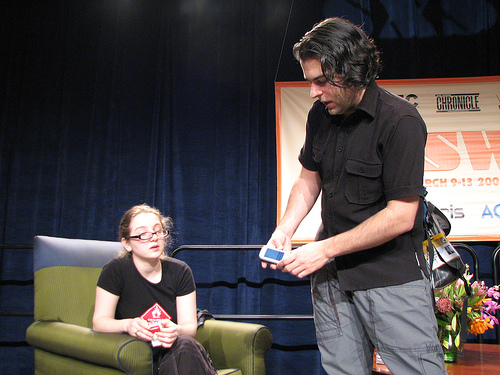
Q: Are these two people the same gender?
A: No, they are both male and female.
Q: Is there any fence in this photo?
A: No, there are no fences.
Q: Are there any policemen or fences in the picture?
A: No, there are no fences or policemen.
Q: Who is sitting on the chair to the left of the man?
A: The girl is sitting on the chair.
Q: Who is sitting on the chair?
A: The girl is sitting on the chair.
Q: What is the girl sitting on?
A: The girl is sitting on the chair.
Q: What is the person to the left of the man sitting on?
A: The girl is sitting on the chair.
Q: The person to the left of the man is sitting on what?
A: The girl is sitting on the chair.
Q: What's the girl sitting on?
A: The girl is sitting on the chair.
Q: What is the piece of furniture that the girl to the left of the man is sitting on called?
A: The piece of furniture is a chair.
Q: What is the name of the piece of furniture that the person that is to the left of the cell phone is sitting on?
A: The piece of furniture is a chair.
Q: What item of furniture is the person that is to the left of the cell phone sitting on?
A: The girl is sitting on the chair.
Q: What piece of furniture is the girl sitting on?
A: The girl is sitting on the chair.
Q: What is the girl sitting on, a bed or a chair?
A: The girl is sitting on a chair.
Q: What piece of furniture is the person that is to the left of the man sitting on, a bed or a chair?
A: The girl is sitting on a chair.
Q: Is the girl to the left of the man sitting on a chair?
A: Yes, the girl is sitting on a chair.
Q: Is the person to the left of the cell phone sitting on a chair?
A: Yes, the girl is sitting on a chair.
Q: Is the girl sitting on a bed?
A: No, the girl is sitting on a chair.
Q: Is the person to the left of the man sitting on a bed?
A: No, the girl is sitting on a chair.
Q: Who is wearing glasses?
A: The girl is wearing glasses.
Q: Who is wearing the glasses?
A: The girl is wearing glasses.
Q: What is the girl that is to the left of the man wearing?
A: The girl is wearing glasses.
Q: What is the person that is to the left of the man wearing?
A: The girl is wearing glasses.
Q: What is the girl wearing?
A: The girl is wearing glasses.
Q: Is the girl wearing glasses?
A: Yes, the girl is wearing glasses.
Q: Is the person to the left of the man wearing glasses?
A: Yes, the girl is wearing glasses.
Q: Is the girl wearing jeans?
A: No, the girl is wearing glasses.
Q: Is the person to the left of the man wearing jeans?
A: No, the girl is wearing glasses.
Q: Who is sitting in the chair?
A: The girl is sitting in the chair.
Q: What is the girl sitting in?
A: The girl is sitting in the chair.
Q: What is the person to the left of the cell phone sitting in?
A: The girl is sitting in the chair.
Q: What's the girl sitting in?
A: The girl is sitting in the chair.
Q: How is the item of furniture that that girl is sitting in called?
A: The piece of furniture is a chair.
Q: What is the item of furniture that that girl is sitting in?
A: The piece of furniture is a chair.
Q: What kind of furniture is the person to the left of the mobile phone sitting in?
A: The girl is sitting in the chair.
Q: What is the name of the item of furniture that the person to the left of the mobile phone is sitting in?
A: The piece of furniture is a chair.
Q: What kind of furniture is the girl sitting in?
A: The girl is sitting in the chair.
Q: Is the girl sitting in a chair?
A: Yes, the girl is sitting in a chair.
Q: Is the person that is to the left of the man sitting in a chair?
A: Yes, the girl is sitting in a chair.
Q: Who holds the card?
A: The girl holds the card.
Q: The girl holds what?
A: The girl holds the card.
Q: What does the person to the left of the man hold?
A: The girl holds the card.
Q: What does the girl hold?
A: The girl holds the card.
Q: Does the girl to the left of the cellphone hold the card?
A: Yes, the girl holds the card.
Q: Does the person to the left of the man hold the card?
A: Yes, the girl holds the card.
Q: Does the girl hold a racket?
A: No, the girl holds the card.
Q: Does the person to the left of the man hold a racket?
A: No, the girl holds the card.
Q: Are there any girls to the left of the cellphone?
A: Yes, there is a girl to the left of the cellphone.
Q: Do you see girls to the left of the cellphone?
A: Yes, there is a girl to the left of the cellphone.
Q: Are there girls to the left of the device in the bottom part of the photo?
A: Yes, there is a girl to the left of the cellphone.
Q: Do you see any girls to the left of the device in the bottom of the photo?
A: Yes, there is a girl to the left of the cellphone.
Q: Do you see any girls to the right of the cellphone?
A: No, the girl is to the left of the cellphone.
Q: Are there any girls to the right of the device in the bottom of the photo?
A: No, the girl is to the left of the cellphone.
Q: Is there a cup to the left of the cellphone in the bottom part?
A: No, there is a girl to the left of the cellphone.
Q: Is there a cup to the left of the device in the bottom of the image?
A: No, there is a girl to the left of the cellphone.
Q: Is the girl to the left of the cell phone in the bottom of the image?
A: Yes, the girl is to the left of the mobile phone.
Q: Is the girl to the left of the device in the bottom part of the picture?
A: Yes, the girl is to the left of the mobile phone.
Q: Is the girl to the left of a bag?
A: No, the girl is to the left of the mobile phone.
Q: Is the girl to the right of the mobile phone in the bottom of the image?
A: No, the girl is to the left of the mobile phone.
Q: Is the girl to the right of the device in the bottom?
A: No, the girl is to the left of the mobile phone.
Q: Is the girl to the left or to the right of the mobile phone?
A: The girl is to the left of the mobile phone.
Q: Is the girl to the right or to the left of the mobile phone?
A: The girl is to the left of the mobile phone.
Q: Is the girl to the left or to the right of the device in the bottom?
A: The girl is to the left of the mobile phone.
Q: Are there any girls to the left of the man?
A: Yes, there is a girl to the left of the man.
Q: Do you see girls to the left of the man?
A: Yes, there is a girl to the left of the man.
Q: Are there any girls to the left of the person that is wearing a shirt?
A: Yes, there is a girl to the left of the man.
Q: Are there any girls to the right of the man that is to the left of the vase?
A: No, the girl is to the left of the man.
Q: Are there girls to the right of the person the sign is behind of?
A: No, the girl is to the left of the man.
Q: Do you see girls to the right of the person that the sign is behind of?
A: No, the girl is to the left of the man.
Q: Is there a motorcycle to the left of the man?
A: No, there is a girl to the left of the man.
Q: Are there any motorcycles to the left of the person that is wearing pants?
A: No, there is a girl to the left of the man.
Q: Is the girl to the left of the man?
A: Yes, the girl is to the left of the man.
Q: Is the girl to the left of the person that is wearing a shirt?
A: Yes, the girl is to the left of the man.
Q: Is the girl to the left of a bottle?
A: No, the girl is to the left of the man.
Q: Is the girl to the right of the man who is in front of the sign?
A: No, the girl is to the left of the man.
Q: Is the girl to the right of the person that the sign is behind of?
A: No, the girl is to the left of the man.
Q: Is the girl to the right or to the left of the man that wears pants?
A: The girl is to the left of the man.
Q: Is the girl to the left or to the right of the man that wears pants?
A: The girl is to the left of the man.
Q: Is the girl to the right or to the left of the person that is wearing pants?
A: The girl is to the left of the man.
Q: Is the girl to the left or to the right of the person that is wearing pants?
A: The girl is to the left of the man.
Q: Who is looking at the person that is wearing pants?
A: The girl is looking at the man.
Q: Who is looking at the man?
A: The girl is looking at the man.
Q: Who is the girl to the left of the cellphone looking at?
A: The girl is looking at the man.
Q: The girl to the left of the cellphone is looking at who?
A: The girl is looking at the man.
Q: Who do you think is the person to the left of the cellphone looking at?
A: The girl is looking at the man.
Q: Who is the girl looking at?
A: The girl is looking at the man.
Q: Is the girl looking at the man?
A: Yes, the girl is looking at the man.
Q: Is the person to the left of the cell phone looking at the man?
A: Yes, the girl is looking at the man.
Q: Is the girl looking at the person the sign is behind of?
A: Yes, the girl is looking at the man.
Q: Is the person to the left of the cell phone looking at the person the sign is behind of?
A: Yes, the girl is looking at the man.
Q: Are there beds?
A: No, there are no beds.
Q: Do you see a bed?
A: No, there are no beds.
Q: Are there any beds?
A: No, there are no beds.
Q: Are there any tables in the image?
A: Yes, there is a table.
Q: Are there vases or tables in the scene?
A: Yes, there is a table.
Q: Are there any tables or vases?
A: Yes, there is a table.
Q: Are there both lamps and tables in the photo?
A: No, there is a table but no lamps.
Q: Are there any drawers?
A: No, there are no drawers.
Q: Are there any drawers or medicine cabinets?
A: No, there are no drawers or medicine cabinets.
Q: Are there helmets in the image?
A: No, there are no helmets.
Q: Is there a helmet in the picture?
A: No, there are no helmets.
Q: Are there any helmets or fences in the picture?
A: No, there are no helmets or fences.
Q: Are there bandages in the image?
A: No, there are no bandages.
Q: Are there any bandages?
A: No, there are no bandages.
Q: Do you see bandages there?
A: No, there are no bandages.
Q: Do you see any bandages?
A: No, there are no bandages.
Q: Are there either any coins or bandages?
A: No, there are no bandages or coins.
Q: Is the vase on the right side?
A: Yes, the vase is on the right of the image.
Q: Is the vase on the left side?
A: No, the vase is on the right of the image.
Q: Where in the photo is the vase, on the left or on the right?
A: The vase is on the right of the image.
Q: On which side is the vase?
A: The vase is on the right of the image.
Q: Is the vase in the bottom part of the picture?
A: Yes, the vase is in the bottom of the image.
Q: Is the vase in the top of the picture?
A: No, the vase is in the bottom of the image.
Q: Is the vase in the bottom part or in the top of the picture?
A: The vase is in the bottom of the image.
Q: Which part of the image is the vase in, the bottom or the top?
A: The vase is in the bottom of the image.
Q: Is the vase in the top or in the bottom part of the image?
A: The vase is in the bottom of the image.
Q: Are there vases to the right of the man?
A: Yes, there is a vase to the right of the man.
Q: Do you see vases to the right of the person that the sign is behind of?
A: Yes, there is a vase to the right of the man.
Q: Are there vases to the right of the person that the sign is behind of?
A: Yes, there is a vase to the right of the man.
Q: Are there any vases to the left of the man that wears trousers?
A: No, the vase is to the right of the man.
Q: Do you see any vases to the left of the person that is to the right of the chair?
A: No, the vase is to the right of the man.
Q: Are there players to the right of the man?
A: No, there is a vase to the right of the man.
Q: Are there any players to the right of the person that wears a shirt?
A: No, there is a vase to the right of the man.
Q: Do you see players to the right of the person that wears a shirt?
A: No, there is a vase to the right of the man.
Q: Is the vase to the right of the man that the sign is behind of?
A: Yes, the vase is to the right of the man.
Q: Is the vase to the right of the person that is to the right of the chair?
A: Yes, the vase is to the right of the man.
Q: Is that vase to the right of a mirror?
A: No, the vase is to the right of the man.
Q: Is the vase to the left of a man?
A: No, the vase is to the right of a man.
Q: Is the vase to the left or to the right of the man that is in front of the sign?
A: The vase is to the right of the man.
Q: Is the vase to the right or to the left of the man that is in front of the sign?
A: The vase is to the right of the man.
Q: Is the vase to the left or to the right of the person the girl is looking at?
A: The vase is to the right of the man.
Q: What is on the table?
A: The vase is on the table.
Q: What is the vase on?
A: The vase is on the table.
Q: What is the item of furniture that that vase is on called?
A: The piece of furniture is a table.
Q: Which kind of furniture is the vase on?
A: The vase is on the table.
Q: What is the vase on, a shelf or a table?
A: The vase is on a table.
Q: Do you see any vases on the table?
A: Yes, there is a vase on the table.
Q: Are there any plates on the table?
A: No, there is a vase on the table.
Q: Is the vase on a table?
A: Yes, the vase is on a table.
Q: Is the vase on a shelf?
A: No, the vase is on a table.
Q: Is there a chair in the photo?
A: Yes, there is a chair.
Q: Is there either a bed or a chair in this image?
A: Yes, there is a chair.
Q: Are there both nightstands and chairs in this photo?
A: No, there is a chair but no nightstands.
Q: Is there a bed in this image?
A: No, there are no beds.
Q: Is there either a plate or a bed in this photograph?
A: No, there are no beds or plates.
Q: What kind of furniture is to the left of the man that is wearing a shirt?
A: The piece of furniture is a chair.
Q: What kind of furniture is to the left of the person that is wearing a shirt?
A: The piece of furniture is a chair.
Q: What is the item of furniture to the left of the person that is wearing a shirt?
A: The piece of furniture is a chair.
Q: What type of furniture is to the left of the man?
A: The piece of furniture is a chair.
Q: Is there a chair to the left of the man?
A: Yes, there is a chair to the left of the man.